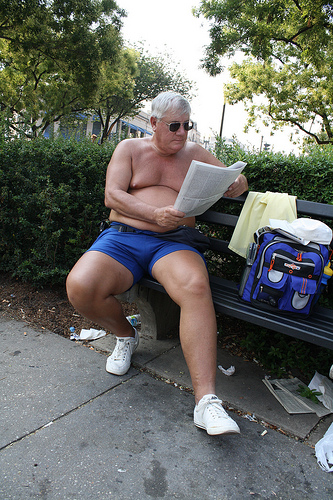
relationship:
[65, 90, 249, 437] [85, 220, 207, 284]
man in shorts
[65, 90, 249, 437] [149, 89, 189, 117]
man has hair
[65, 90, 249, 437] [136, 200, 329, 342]
man sitting on bench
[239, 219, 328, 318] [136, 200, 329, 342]
bag on top of bench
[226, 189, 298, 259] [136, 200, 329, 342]
shirt folded on bench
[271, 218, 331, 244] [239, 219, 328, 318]
cap sitting on bag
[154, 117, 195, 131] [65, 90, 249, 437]
sunglasses worn by man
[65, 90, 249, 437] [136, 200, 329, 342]
man on bench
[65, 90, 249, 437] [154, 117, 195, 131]
man has sunglasses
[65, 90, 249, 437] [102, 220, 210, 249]
man has fanny pack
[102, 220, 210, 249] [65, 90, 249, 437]
fanny pack worn by man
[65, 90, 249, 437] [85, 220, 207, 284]
man has shorts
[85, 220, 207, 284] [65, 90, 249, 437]
shorts worn by man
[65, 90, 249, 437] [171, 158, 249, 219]
man reading newspaper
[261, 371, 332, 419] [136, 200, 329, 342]
newspaper under bench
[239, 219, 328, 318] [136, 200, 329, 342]
bag sitting on bench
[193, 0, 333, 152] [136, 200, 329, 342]
trees behind bench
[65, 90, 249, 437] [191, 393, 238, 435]
man wearing tennis shoe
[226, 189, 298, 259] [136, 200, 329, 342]
shirt hanging on bench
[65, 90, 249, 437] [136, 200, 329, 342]
man on park bench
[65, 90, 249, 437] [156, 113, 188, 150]
man has face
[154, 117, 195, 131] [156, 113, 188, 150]
sunglasses on face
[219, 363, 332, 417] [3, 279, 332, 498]
trash on pavement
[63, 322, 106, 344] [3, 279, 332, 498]
trash on pavement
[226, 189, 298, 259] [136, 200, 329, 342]
shirt resting on bench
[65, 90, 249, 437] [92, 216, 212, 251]
man has waist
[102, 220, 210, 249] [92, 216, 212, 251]
fanny pack around waist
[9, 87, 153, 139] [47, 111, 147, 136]
building with awnings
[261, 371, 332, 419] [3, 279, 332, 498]
litter on ground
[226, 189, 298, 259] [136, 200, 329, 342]
shirt draped over bench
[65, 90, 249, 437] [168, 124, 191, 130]
man has eyes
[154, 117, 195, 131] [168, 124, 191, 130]
sunglasses on eyes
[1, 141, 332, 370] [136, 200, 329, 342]
bushes behind bench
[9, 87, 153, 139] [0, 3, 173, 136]
building behind trees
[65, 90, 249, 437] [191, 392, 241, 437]
man has foot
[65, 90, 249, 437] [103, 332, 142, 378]
man has foot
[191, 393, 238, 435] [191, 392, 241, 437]
tennis shoe on foot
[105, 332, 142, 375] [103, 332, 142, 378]
tennis shoe on foot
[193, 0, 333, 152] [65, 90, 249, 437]
trees behind man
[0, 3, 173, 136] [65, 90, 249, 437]
trees behind man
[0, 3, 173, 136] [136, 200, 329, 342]
trees behind bench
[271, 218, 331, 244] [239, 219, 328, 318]
cap on top of backpack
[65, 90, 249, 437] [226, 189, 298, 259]
man without shirt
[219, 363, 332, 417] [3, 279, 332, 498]
trash on ground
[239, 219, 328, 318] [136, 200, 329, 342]
backpack sitting on bench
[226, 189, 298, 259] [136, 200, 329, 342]
shirt draped on bench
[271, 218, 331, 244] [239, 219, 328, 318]
cap laying on backpack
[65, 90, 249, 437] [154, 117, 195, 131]
man wearing sunglasses